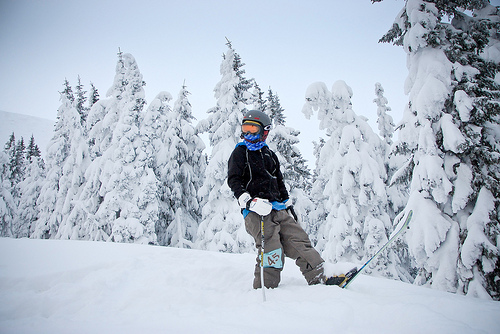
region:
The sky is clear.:
[14, 14, 94, 56]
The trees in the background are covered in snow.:
[56, 49, 166, 238]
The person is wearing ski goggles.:
[236, 107, 270, 143]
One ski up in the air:
[316, 206, 416, 288]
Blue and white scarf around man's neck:
[239, 133, 266, 149]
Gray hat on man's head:
[243, 108, 270, 132]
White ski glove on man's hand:
[236, 190, 273, 215]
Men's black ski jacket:
[226, 145, 291, 217]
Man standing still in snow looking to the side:
[226, 109, 413, 291]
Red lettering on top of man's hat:
[243, 112, 260, 120]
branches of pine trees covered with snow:
[2, 7, 494, 297]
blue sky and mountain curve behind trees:
[6, 7, 423, 175]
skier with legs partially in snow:
[220, 105, 416, 300]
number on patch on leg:
[245, 212, 281, 288]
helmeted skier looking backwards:
[225, 105, 330, 285]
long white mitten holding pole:
[235, 187, 270, 297]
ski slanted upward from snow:
[306, 198, 416, 288]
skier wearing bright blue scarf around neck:
[238, 117, 273, 152]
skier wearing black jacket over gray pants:
[225, 140, 325, 287]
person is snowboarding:
[230, 108, 411, 295]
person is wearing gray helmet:
[224, 109, 344, 288]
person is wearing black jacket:
[226, 143, 292, 205]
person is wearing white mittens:
[250, 199, 272, 214]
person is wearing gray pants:
[243, 208, 324, 287]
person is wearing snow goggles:
[241, 123, 260, 132]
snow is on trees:
[0, 1, 498, 298]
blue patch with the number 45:
[260, 248, 281, 267]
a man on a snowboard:
[215, 104, 417, 292]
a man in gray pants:
[220, 104, 417, 295]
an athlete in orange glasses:
[221, 105, 416, 297]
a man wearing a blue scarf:
[221, 114, 415, 292]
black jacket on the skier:
[224, 140, 291, 208]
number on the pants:
[257, 245, 283, 270]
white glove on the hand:
[238, 189, 275, 220]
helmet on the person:
[236, 105, 273, 146]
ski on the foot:
[335, 195, 418, 296]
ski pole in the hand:
[247, 202, 275, 307]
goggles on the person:
[234, 109, 276, 152]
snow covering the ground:
[0, 219, 497, 331]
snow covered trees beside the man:
[2, 0, 498, 295]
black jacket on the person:
[222, 108, 302, 225]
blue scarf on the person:
[225, 105, 277, 152]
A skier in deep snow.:
[225, 100, 417, 298]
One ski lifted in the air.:
[333, 208, 417, 300]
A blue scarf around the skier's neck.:
[226, 108, 285, 160]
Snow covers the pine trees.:
[31, 43, 486, 285]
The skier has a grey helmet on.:
[217, 103, 419, 289]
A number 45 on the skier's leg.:
[257, 244, 287, 269]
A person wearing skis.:
[221, 110, 421, 285]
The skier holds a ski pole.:
[221, 101, 414, 302]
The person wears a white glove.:
[241, 190, 278, 218]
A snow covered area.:
[11, 236, 493, 331]